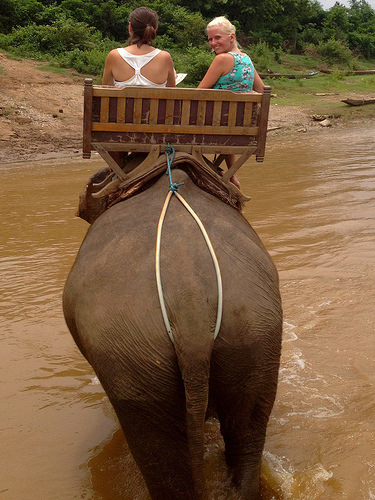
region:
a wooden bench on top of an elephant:
[80, 78, 270, 209]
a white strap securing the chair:
[154, 186, 223, 351]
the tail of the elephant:
[174, 341, 214, 499]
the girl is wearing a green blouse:
[218, 49, 256, 91]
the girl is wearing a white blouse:
[113, 45, 168, 88]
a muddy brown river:
[281, 132, 374, 498]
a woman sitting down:
[195, 16, 265, 91]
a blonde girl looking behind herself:
[195, 11, 264, 90]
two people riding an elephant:
[83, 6, 263, 88]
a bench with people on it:
[81, 6, 270, 162]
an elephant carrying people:
[61, 6, 280, 493]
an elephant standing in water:
[60, 163, 307, 495]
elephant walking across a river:
[51, 159, 348, 494]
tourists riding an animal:
[63, 5, 282, 495]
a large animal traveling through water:
[58, 158, 292, 496]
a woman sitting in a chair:
[100, 3, 178, 108]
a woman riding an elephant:
[202, 13, 354, 233]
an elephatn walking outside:
[78, 176, 333, 491]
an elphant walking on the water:
[70, 186, 281, 389]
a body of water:
[289, 322, 346, 499]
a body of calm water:
[287, 330, 369, 493]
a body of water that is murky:
[272, 358, 372, 466]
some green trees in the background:
[4, 0, 370, 87]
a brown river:
[3, 105, 371, 498]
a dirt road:
[0, 23, 317, 163]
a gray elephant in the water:
[4, 5, 371, 498]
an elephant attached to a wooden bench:
[38, 74, 326, 497]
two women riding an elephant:
[58, 0, 311, 498]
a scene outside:
[3, 2, 370, 493]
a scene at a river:
[9, 10, 370, 486]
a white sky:
[305, 0, 373, 17]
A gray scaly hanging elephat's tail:
[178, 351, 219, 490]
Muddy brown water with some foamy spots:
[302, 374, 365, 482]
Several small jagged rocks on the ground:
[314, 108, 337, 131]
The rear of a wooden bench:
[78, 80, 274, 155]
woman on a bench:
[195, 13, 265, 89]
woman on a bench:
[105, 7, 184, 95]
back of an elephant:
[50, 153, 289, 498]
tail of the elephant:
[169, 305, 220, 493]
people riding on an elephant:
[54, 7, 300, 497]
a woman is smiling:
[185, 4, 266, 95]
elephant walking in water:
[14, 8, 370, 489]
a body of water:
[3, 114, 374, 499]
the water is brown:
[8, 122, 373, 493]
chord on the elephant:
[153, 185, 234, 368]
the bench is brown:
[71, 63, 291, 176]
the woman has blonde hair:
[203, 14, 240, 61]